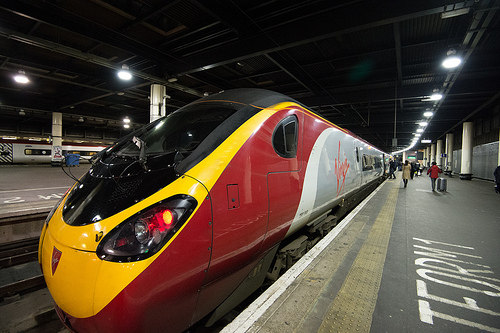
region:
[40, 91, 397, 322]
a red yellow and grey train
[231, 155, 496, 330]
a train boarding platform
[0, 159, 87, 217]
a train boarding platform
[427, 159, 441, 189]
a person on platform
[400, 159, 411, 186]
a person waiting on platform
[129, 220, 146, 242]
a train front headlight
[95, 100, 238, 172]
a train front windshield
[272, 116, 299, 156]
a train engine side window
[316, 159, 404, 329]
a long yellow painted line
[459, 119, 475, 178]
a white pillar in distance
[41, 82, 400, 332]
Train on the tracks.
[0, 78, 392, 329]
Red, yellow, white and gray colors on the train.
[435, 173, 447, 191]
Silver luggage bag.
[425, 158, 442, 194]
Person in red jacket.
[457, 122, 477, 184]
White columns bracing ceiling.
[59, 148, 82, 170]
Blue container in the background.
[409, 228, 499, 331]
White writing on the cement.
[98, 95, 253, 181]
Window in the front of the train.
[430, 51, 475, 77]
White ceiling light.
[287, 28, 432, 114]
Metal beams on ceiling.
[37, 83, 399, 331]
A red,white, yellow and gray train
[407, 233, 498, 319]
FORM1 on the gray ground.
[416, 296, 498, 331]
Large white T on the ground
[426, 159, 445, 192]
Woman in red jacket walking away.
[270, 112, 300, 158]
Odd shaped first side window of a train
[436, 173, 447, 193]
Small silver trashcan beside a red coat woman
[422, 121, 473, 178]
Six large support pillars to the right of a train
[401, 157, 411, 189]
Woman with dark hair walking away in a tan coat.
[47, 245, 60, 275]
Red Virgin triangle on the front of a train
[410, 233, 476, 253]
Number 1 on the ground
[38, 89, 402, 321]
The train is yellow, red, and silver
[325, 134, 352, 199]
Red writing on side of train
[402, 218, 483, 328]
White letters on station platform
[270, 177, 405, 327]
Faded yellow stripe on station platform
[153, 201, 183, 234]
Round orange light on front of train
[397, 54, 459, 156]
Row of lights down platform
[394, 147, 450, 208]
People are walking on the station platform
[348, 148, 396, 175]
Long black windows on the side of the train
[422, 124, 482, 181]
Row of large white columns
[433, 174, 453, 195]
The suit case is grey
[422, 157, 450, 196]
Person in a red top with a suitcase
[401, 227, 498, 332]
White sign on the platform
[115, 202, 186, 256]
Bright red headlight of the train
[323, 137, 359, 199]
Red Virgin logo on the side of the train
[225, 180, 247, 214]
Metal train compartment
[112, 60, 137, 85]
Bright white light on the ceiling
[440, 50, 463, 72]
Bright white light on the ceiling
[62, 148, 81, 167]
Light blue box on the other side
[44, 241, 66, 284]
Red triangle on the front of the train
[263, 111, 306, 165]
Black window on the side of the train